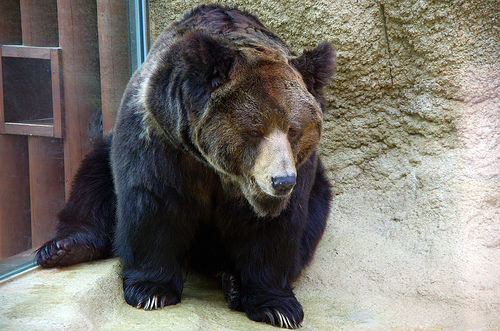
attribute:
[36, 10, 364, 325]
bear — sitting, brown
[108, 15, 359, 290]
bear — brown, black 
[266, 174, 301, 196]
nose — Black 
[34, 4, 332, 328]
bear — black , brown, sitting, large , fur 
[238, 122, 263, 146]
eye — bear's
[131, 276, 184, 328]
claws — bears , long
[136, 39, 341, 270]
bear — sitting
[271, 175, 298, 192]
nose — bear's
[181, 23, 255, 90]
ear — bear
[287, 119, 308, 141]
eye — bear's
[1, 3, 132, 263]
wall — red 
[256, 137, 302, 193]
snout — tan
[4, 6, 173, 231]
racks — wood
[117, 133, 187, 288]
hair — white , Black 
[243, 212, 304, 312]
hair — white , Black 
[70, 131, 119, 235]
hair — white , Black 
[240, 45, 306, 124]
hair — white , Black 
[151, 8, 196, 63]
hair — white , Black 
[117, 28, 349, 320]
rock — tan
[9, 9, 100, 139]
structure — made of logs